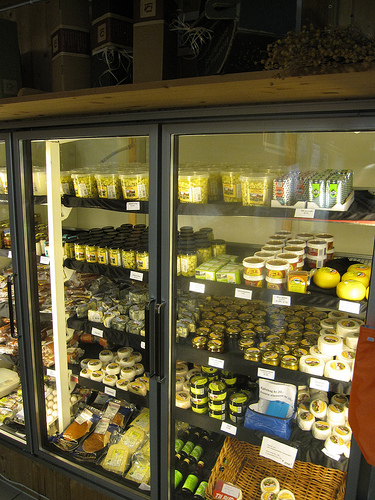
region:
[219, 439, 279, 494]
basket in the bottom of the cooler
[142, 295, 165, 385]
black handles on the cooler door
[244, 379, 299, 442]
blue pouch in the cooler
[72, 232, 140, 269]
small glass jars in the cooler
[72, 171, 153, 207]
clear plastic container in the cooler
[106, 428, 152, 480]
plastic wrapped goods in the cooler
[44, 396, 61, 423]
eggs in the cooler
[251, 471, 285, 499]
small items in wicker basket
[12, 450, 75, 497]
bottom of the cooler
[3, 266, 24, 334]
single cooler handle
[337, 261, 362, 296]
Yellow cheeses on a refrigerated shelf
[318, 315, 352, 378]
White cheeses on a refrigerated shelf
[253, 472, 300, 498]
Cheeses in a wicker basket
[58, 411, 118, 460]
Ready-made sandwiches wrapped in plastic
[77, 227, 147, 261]
Group of jars with black lids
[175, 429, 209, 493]
Bottles with green labels and yellow lids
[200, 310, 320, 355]
Small jars with gold lids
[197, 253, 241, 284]
Group of green boxes on refrigerated shelf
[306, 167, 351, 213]
Group of packages with green labels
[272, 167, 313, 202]
Group of packages with orange labels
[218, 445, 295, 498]
brown wicker basket on the bottom of the cooler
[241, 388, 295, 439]
blue bag in the cooler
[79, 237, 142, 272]
small clear bottles in the cooler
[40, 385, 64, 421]
eggs in the cooler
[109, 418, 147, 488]
goods wrapped in plastic in the cooler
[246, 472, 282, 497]
small items in the brown basket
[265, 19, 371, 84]
small flowers on top of the cooler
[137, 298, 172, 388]
two black cooler door handles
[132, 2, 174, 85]
box on top of the cooler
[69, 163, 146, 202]
clear plastic container of goods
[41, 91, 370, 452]
a fridge with food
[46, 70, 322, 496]
food in a fridge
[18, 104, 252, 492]
cold food in a fridge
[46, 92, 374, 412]
food on display in store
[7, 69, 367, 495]
food on display in fridge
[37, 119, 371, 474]
cold food on display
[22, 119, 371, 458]
cold food on display in fridge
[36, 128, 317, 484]
food for sale in store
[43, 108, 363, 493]
cold food for sale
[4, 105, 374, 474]
food for sale in fridge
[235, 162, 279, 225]
Small container of food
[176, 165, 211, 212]
Small container of food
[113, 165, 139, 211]
Small container of food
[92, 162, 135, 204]
Small container of food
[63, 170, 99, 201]
Small container of food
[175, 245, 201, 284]
Small container of food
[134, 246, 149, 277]
Small container of food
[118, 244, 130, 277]
Small container of food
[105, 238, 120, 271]
Small container of food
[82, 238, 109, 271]
Small container of food